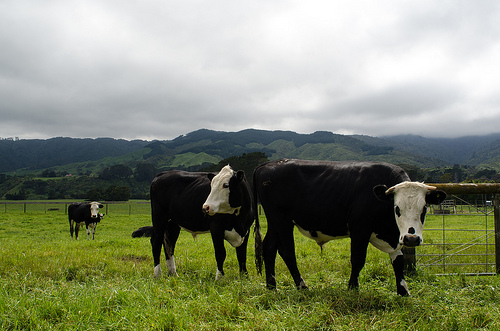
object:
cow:
[67, 201, 103, 240]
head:
[88, 200, 104, 220]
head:
[200, 164, 244, 216]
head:
[373, 181, 447, 246]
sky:
[2, 1, 499, 139]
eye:
[221, 183, 232, 189]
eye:
[394, 207, 400, 217]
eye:
[422, 206, 426, 218]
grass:
[3, 214, 499, 331]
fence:
[1, 200, 495, 218]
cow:
[143, 161, 255, 287]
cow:
[251, 157, 450, 296]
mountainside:
[2, 127, 500, 198]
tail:
[250, 163, 266, 277]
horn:
[425, 183, 439, 193]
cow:
[131, 226, 153, 239]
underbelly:
[294, 224, 398, 253]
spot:
[407, 223, 418, 235]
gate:
[411, 192, 498, 276]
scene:
[1, 2, 498, 330]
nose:
[402, 234, 422, 247]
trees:
[106, 162, 136, 179]